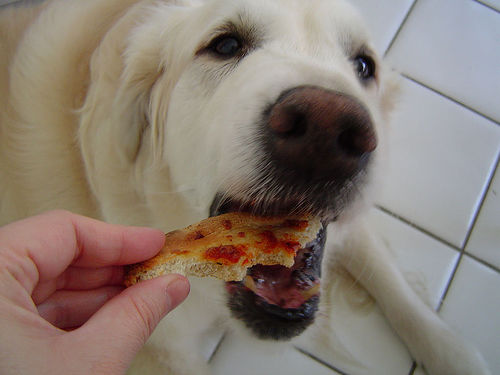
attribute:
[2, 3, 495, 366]
dog — white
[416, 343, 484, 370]
paw — white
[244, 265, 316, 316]
tongue — pink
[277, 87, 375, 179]
nose — black, brown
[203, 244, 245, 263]
sauce — red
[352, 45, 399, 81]
eye — dark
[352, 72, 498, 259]
tiles — white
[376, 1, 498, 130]
tiles — white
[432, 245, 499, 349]
tiles — white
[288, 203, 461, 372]
tiles — white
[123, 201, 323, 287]
crust — pizza